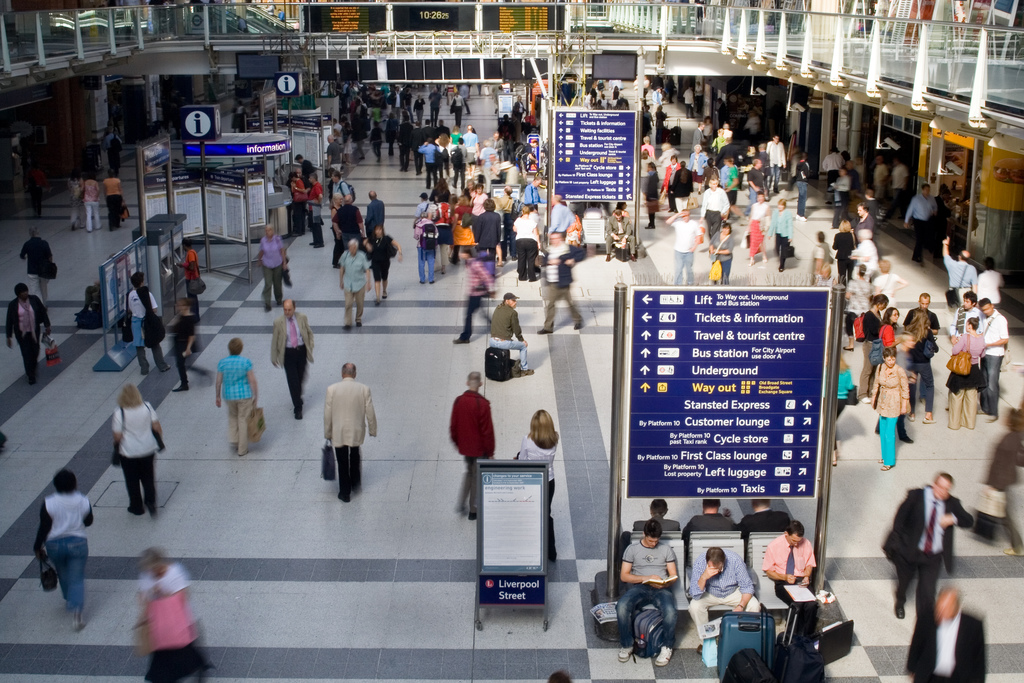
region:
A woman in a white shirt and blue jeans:
[34, 467, 93, 627]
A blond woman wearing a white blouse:
[108, 383, 165, 514]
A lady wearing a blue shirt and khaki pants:
[215, 336, 264, 457]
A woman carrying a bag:
[215, 336, 266, 457]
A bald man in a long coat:
[319, 361, 377, 501]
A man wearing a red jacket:
[451, 370, 494, 517]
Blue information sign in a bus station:
[623, 284, 830, 500]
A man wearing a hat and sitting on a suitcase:
[484, 293, 535, 382]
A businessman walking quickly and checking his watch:
[881, 471, 974, 617]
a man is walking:
[321, 360, 376, 500]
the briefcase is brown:
[321, 445, 332, 480]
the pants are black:
[332, 447, 361, 495]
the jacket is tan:
[321, 378, 376, 445]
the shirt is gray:
[623, 536, 672, 581]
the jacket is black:
[904, 606, 985, 679]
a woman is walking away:
[35, 469, 96, 629]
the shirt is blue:
[217, 356, 250, 396]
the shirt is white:
[672, 214, 701, 254]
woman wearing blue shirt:
[206, 324, 273, 448]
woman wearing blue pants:
[863, 351, 908, 462]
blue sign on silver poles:
[632, 288, 822, 508]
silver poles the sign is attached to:
[604, 278, 845, 633]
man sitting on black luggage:
[483, 295, 532, 378]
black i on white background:
[186, 104, 209, 140]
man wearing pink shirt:
[764, 513, 823, 593]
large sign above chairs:
[597, 261, 844, 635]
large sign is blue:
[610, 268, 839, 518]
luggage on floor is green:
[705, 600, 783, 674]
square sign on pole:
[168, 93, 226, 152]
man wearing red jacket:
[440, 388, 502, 466]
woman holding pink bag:
[140, 589, 201, 659]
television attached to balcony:
[585, 43, 646, 94]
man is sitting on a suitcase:
[483, 294, 536, 381]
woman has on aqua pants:
[869, 404, 904, 468]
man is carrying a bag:
[318, 362, 378, 501]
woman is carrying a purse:
[944, 325, 980, 429]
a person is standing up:
[124, 536, 198, 679]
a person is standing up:
[109, 387, 160, 504]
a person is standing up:
[447, 361, 490, 510]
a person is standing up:
[512, 411, 566, 558]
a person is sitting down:
[611, 513, 672, 654]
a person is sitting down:
[687, 542, 755, 659]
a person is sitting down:
[769, 522, 818, 658]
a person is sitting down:
[626, 497, 685, 530]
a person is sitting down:
[684, 487, 729, 527]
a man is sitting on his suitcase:
[482, 290, 536, 380]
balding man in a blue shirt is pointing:
[939, 233, 975, 339]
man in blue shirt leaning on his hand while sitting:
[688, 547, 758, 665]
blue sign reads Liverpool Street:
[473, 574, 547, 606]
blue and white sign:
[612, 273, 831, 505]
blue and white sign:
[555, 93, 633, 196]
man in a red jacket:
[452, 337, 497, 533]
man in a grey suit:
[301, 355, 382, 511]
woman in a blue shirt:
[206, 324, 268, 455]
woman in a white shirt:
[95, 356, 179, 502]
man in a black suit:
[898, 574, 979, 666]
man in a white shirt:
[662, 198, 702, 272]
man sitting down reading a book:
[622, 511, 692, 642]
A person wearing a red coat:
[431, 351, 512, 478]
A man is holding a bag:
[304, 342, 394, 520]